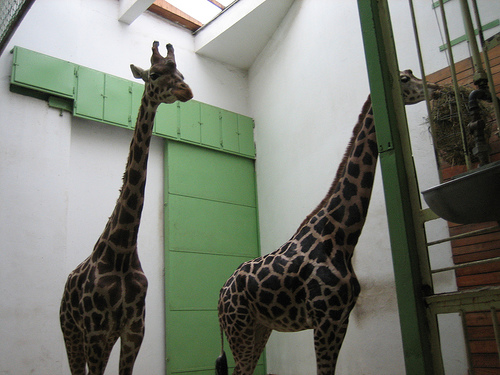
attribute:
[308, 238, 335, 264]
spot — large, brown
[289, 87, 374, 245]
mane — rough, dry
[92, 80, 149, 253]
mane — rough, dry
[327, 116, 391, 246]
neck — long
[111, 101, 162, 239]
neck — long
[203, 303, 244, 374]
tail — giraffes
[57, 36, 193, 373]
giraffe — eating, tall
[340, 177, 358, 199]
spot — large, brown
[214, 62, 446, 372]
giraffe — eating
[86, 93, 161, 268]
neck — long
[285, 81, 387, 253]
neck — long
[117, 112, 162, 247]
neck — long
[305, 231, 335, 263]
spot — brown, large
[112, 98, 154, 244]
neck — long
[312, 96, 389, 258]
neck — long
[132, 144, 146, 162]
spot — large, brown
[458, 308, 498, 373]
wood paneling — brown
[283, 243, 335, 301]
spots — dark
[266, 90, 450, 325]
giraffe — eating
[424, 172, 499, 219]
bowl — dark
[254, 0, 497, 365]
wall — white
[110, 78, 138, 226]
mane — short, dark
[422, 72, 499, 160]
hay — dry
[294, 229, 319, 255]
spot — large, brown